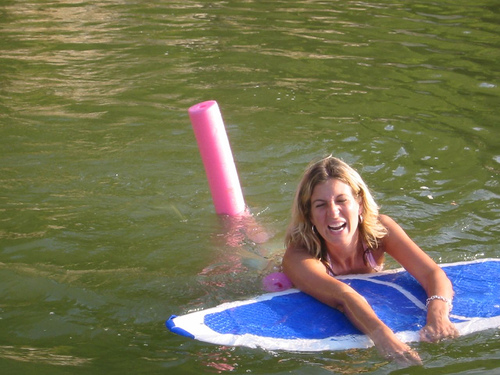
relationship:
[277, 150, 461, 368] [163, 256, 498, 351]
blond woman on surfboard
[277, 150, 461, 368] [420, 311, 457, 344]
blond woman has hand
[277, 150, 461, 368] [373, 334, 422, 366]
blond woman has hand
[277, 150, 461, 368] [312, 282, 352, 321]
blond woman has elbow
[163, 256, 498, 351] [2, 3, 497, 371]
surfboard in water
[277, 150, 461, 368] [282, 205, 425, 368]
blond woman has arm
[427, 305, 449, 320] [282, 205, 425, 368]
wrist on arm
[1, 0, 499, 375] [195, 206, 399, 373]
green water has reflection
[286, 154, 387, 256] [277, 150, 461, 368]
hair on blond woman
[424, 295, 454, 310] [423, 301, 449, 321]
bracelet on wrist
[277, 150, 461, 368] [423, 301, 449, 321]
blond woman has wrist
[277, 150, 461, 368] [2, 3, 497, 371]
blond woman in water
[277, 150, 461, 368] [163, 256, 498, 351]
blond woman holds surfboard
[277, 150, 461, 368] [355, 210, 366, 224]
blond woman wears earring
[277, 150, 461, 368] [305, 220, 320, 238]
blond woman wears earring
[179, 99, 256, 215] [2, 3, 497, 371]
pool noodle sticking out of water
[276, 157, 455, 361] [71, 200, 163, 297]
blond woman in water